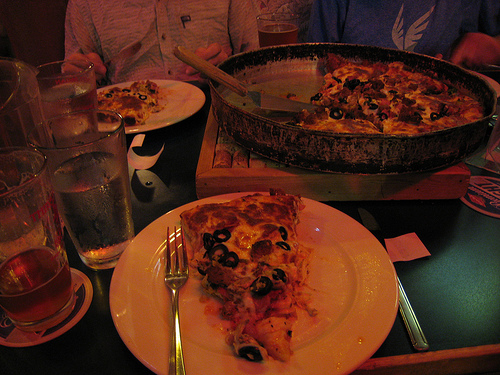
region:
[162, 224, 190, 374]
a fork on a plate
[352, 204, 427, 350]
a knife on a table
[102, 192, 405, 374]
a plate on a table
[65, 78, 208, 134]
a plate on a table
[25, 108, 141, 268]
a glass on a table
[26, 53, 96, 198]
a glass on a table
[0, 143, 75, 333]
a glass on a table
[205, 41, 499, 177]
a metal pan full of pizza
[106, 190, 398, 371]
a plate of pizza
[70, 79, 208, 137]
a plate of pizza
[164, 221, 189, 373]
a silver dinner fork on a white plate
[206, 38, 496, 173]
a large deep dish pizza pan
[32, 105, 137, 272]
a glass half full of refreshing water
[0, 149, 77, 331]
a nearly empty glass of ice cold beer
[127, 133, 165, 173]
a curled up receipt on the table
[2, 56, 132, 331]
a pitcher and three drinking glasses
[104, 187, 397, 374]
a white plate holding one piece of pizza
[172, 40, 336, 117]
a pizza server with a wooden handle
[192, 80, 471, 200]
a large wooden trivet holding a pizza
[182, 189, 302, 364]
a piece of deep dish pizza with black olives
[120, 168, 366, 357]
pizza on the plate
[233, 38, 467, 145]
pizza in the pan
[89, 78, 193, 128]
pizza on the plate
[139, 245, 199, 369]
fork on the plate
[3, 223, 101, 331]
liquid in the glass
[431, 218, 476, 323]
the table is green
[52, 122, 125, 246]
water in the glass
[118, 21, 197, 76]
shirt of the man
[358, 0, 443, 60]
symbol on the shirt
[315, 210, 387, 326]
the plate is glass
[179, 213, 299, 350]
pizza slice on plate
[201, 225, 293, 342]
black olives on plate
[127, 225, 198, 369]
silver fork on plate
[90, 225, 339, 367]
plate on green table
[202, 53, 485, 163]
pizza in black pan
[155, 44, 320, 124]
brown handle on spatula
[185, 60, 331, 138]
spatula is in pizza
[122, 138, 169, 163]
wrapping paper on table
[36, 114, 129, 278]
clear glass with water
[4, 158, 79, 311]
clear glass with beer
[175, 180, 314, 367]
a piece of pizza on a plate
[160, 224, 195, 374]
a fork on a plate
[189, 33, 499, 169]
a pizza in a pizza pan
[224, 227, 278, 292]
the toppings of a pizza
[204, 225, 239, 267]
sliced olives on a pizza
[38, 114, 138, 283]
water in a glass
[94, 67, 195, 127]
a piece of pizza on a plate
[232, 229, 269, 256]
the melted cheese of a pizza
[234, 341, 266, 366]
a slice of black olive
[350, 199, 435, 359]
a table knife by a plate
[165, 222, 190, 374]
the fork has three prongs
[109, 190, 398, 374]
the fork is on the plate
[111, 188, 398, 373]
the pizza is on the plate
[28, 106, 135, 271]
the cup is clear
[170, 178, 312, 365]
pizza on yellow plate